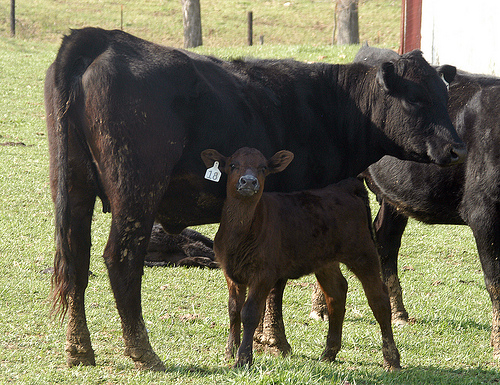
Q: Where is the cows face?
A: Against another cow.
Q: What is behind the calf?
A: Adult cow.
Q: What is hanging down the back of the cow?
A: Tail.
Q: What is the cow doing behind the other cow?
A: Laying down.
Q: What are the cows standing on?
A: Grass.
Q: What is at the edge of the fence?
A: Various size posts.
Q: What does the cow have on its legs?
A: Knobs and protrusionns.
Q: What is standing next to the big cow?
A: Calf.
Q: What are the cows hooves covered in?
A: Mud.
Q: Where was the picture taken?
A: In a pasture.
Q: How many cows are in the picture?
A: 4.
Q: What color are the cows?
A: Black.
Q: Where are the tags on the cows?
A: On ears.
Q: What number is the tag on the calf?
A: 18.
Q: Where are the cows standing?
A: On the grass.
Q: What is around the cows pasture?
A: A fence.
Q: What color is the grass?
A: Green.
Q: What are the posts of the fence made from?
A: Wood.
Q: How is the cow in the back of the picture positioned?
A: Laying down.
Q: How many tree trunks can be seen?
A: 2.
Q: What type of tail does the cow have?
A: Long black tail.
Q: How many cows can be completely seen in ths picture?
A: 2.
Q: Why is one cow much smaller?
A: It's a baby.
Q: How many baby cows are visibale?
A: 1.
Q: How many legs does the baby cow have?
A: 4.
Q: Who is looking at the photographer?
A: Baby cow.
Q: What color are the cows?
A: Black.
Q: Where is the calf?
A: By its mother.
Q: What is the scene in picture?
A: Cows in pasture.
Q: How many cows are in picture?
A: 4.